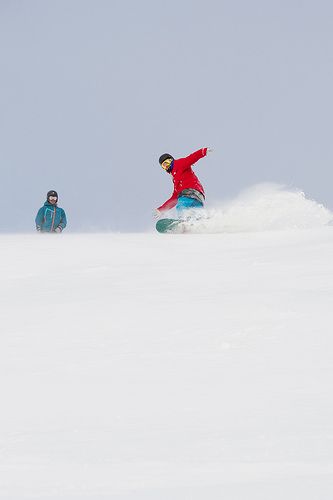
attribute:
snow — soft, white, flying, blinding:
[4, 180, 329, 499]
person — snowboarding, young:
[159, 144, 208, 220]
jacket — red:
[159, 150, 206, 212]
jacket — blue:
[36, 203, 67, 233]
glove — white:
[54, 227, 59, 235]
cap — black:
[158, 155, 172, 163]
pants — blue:
[175, 198, 202, 212]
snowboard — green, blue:
[156, 220, 179, 235]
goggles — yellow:
[161, 159, 173, 168]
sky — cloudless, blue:
[0, 2, 331, 229]